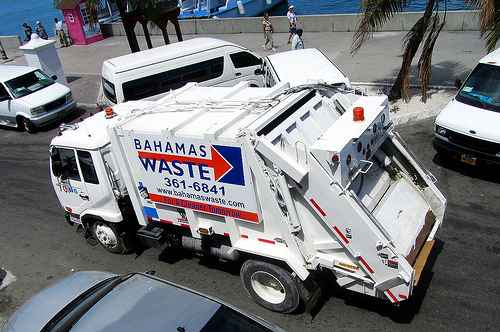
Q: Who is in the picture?
A: People on the sidewalk.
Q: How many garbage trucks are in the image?
A: One.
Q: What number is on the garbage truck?
A: 361-6841.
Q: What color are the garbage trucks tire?
A: Black.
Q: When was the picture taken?
A: During the day.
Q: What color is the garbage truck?
A: White.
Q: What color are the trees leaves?
A: Green.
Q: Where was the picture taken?
A: On the street.